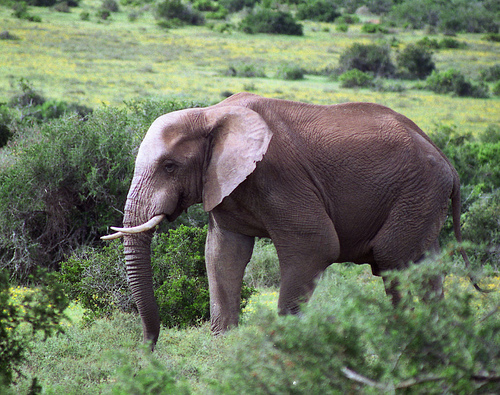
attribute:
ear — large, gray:
[199, 108, 274, 214]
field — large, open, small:
[1, 3, 491, 393]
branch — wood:
[36, 187, 118, 262]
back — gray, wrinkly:
[281, 89, 418, 146]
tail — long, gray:
[451, 157, 475, 294]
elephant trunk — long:
[115, 209, 177, 366]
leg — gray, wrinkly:
[255, 211, 337, 335]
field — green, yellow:
[0, 0, 499, 144]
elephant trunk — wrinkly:
[124, 185, 164, 377]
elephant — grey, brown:
[86, 93, 496, 368]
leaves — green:
[30, 123, 90, 164]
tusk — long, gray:
[110, 212, 161, 239]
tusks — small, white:
[97, 215, 169, 238]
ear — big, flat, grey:
[203, 112, 278, 205]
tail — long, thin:
[450, 167, 473, 268]